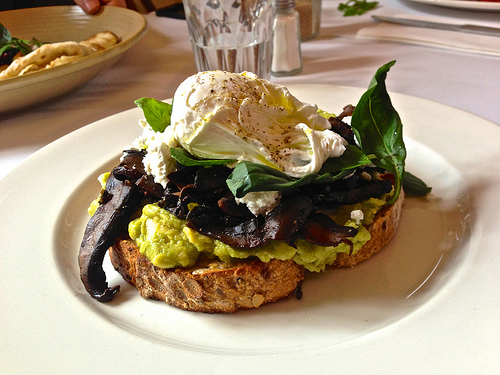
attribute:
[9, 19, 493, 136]
table — white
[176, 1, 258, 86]
glass — clear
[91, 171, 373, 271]
guacamole — green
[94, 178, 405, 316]
bread — brown, whole grain